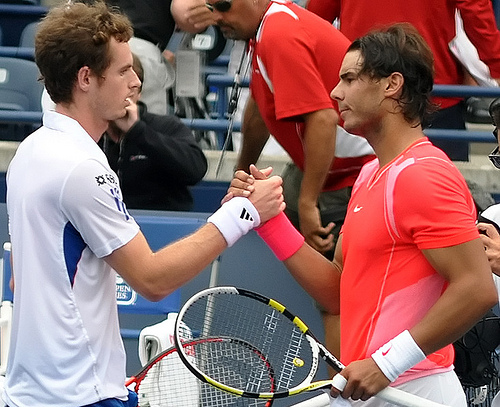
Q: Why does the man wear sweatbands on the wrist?
A: Sweating.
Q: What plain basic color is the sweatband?
A: White.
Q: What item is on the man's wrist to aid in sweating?
A: Sweatband.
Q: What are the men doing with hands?
A: Shaking.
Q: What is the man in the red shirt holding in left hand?
A: Racket.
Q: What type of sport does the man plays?
A: Tennis.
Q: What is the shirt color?
A: Red.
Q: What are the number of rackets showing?
A: Two.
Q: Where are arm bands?
A: Around player's wrists.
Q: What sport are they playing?
A: Tennis.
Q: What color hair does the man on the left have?
A: Brown.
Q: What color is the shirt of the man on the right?
A: Red.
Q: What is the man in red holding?
A: A tennis racket.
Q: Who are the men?
A: Tennis players.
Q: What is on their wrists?
A: Wristbands.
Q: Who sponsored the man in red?
A: Nike.